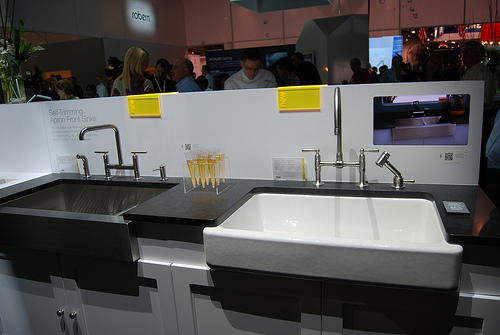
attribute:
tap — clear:
[305, 88, 371, 183]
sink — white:
[190, 182, 465, 299]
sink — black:
[3, 168, 173, 280]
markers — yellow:
[126, 88, 181, 120]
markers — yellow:
[276, 82, 326, 111]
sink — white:
[239, 193, 454, 285]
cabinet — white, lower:
[323, 279, 453, 334]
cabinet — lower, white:
[171, 263, 327, 334]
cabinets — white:
[4, 267, 496, 332]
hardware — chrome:
[55, 307, 78, 320]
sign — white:
[42, 100, 124, 173]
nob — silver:
[54, 309, 64, 316]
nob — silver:
[68, 311, 78, 322]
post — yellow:
[128, 86, 328, 118]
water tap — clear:
[65, 175, 112, 212]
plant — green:
[4, 31, 34, 103]